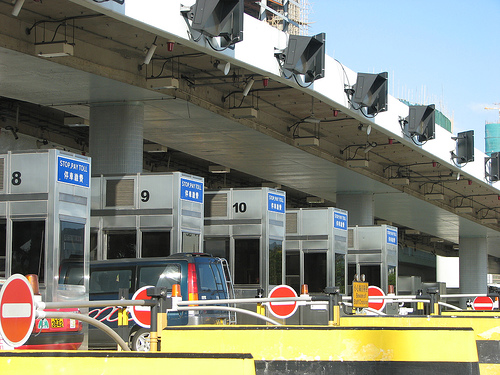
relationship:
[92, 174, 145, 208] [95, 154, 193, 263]
vent on tollbooth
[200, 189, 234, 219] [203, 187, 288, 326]
vent on station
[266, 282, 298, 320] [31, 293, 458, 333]
sign on gates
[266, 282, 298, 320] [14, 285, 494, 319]
sign on gates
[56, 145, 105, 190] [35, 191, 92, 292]
sign on front of stand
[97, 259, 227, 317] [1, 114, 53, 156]
van going into parking lot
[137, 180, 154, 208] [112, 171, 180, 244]
number 9 on booth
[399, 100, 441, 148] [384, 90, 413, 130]
light on wall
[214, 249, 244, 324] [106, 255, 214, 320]
ladder on van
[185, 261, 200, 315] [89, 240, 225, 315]
light on van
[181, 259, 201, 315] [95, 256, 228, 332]
light on van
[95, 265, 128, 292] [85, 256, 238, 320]
window on van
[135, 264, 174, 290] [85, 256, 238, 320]
window on van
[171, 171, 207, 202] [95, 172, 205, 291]
sign on booth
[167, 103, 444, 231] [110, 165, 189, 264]
area above booth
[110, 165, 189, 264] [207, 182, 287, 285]
booth above booth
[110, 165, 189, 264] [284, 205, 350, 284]
booth above booth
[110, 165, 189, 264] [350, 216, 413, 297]
booth above booth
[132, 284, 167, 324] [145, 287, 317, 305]
sign on pole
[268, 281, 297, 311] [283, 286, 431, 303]
sign on pole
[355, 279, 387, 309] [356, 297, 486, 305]
sign on pole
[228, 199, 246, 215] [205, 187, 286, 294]
number on station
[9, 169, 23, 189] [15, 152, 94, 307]
number on station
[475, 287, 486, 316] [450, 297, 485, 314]
sign on pole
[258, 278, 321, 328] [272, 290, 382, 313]
sign on pole